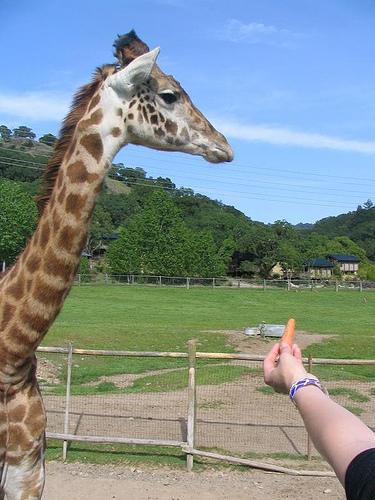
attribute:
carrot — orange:
[277, 317, 304, 352]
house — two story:
[304, 253, 360, 279]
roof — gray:
[302, 252, 359, 264]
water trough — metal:
[243, 320, 286, 337]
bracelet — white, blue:
[289, 377, 329, 402]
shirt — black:
[347, 444, 374, 495]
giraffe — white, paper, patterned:
[0, 45, 254, 325]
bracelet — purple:
[273, 376, 339, 400]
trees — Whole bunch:
[146, 196, 281, 264]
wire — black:
[75, 358, 179, 434]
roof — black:
[305, 252, 332, 268]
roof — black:
[326, 252, 358, 261]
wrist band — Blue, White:
[275, 359, 327, 406]